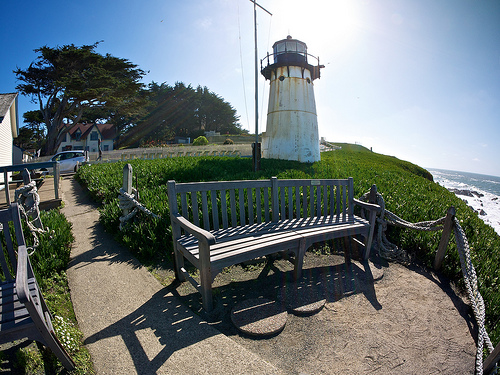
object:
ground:
[74, 141, 499, 310]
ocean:
[421, 167, 499, 238]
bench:
[167, 176, 381, 311]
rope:
[376, 192, 496, 374]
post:
[431, 204, 461, 271]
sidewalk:
[59, 173, 284, 375]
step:
[230, 295, 288, 338]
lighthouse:
[260, 34, 324, 167]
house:
[55, 120, 118, 151]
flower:
[54, 312, 66, 325]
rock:
[453, 186, 475, 196]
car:
[33, 150, 92, 174]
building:
[0, 91, 20, 189]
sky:
[1, 1, 499, 177]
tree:
[13, 38, 168, 160]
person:
[96, 138, 104, 159]